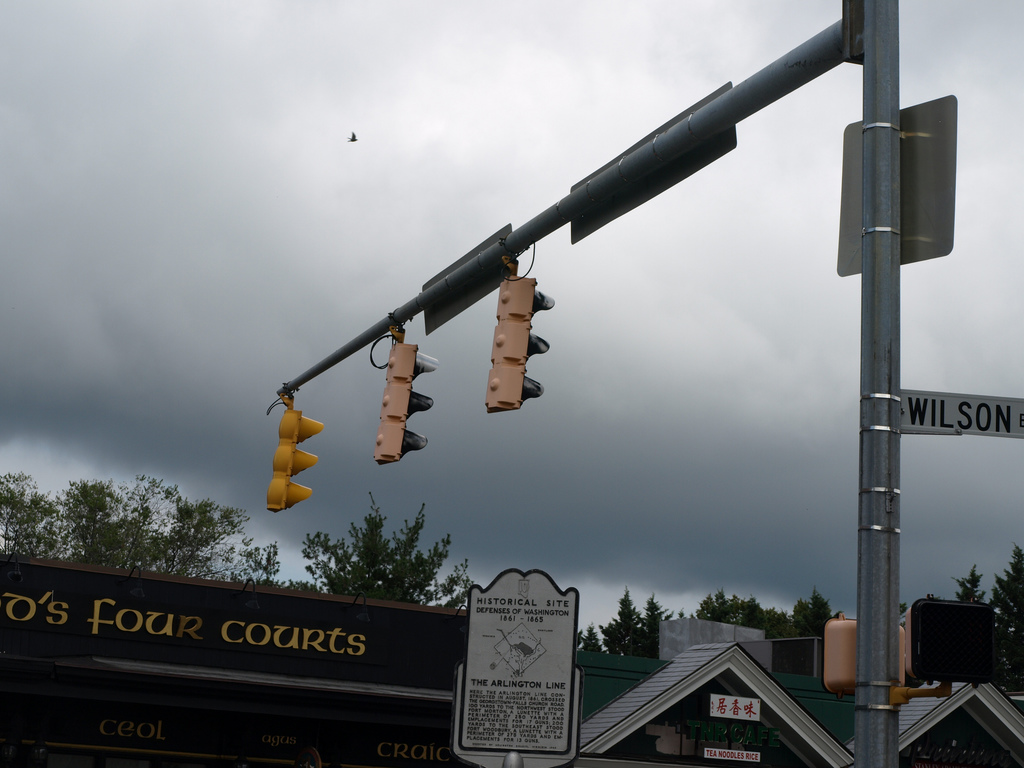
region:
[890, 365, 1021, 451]
The street sign says wilson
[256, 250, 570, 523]
three traffic lights in a row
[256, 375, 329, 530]
bright yellow traffic light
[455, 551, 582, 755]
historical site sign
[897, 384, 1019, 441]
white street sign saying Wilson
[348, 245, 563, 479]
two peach colored traffic signals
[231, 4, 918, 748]
traffic post with three hanging traffic signals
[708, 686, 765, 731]
sign with Asian characters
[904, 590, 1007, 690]
unlit crosswalk signal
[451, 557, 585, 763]
big white sign with black border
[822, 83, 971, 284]
backside of a metal sign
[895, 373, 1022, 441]
a black and white street sign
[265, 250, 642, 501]
a trio of traffic lights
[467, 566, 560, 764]
a sign marking a landmark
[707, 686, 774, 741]
a sign in a foreign language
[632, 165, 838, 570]
cloudy overcast sky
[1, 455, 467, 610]
trees seen over the rooftop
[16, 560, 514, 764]
front of building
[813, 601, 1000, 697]
a walk sign isn't illuminated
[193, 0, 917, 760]
sign at an intersection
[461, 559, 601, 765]
a black and white sign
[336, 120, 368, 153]
unidentified object in sky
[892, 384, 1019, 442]
street sign labeled WILSON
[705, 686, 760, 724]
banner with Chinese symbols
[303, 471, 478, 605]
a tree top behind a building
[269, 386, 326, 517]
a yellow stoplight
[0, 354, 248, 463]
clouds on a bright blue sky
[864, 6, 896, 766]
a steel pole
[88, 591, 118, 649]
The letter 'F'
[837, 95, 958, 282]
the back of a traffic sign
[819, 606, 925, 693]
back of a Walk / Do Not Walk sign.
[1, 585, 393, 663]
Letters on front of building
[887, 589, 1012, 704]
Blank pedestrian crossing sign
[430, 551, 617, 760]
Sign standing on pole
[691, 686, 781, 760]
Chinese letters on building front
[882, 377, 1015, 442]
Street sign on pole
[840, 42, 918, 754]
Silver traffic and light pole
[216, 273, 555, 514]
Three traffic lights hanging from pole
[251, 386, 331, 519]
Yellow traffic light covering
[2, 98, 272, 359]
Cloudy skies of gray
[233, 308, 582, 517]
Three traffic lights side by side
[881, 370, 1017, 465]
A street sign reads "WILSON"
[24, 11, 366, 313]
The sky is very cloudy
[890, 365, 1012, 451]
The street sign is white with black writing on it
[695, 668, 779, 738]
A sign with Asian writing on it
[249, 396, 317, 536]
A traffic light is bright yellow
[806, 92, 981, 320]
The back of a sign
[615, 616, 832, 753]
The top of a building is triangular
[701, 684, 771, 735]
A white sign with red writing on it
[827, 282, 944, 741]
A gray post holds up a sign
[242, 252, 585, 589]
three yellow traffic lights viewed from the side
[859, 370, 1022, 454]
a street sign denoting Wilson Street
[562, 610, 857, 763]
the room of a Chinese restaurant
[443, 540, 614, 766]
a sign marking a historical site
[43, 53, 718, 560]
street lights in front of grey rain clouds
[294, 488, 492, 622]
the top of a green tree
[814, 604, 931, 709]
the back of a "walk/don't walk" signal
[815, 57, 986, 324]
the back side of a street sign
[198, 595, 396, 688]
the word "courts"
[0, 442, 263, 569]
leafy green trees on a cloudy day